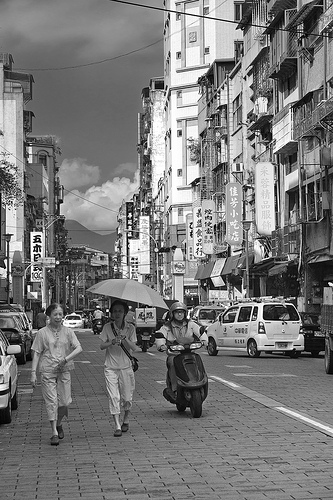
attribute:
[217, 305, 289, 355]
van — white